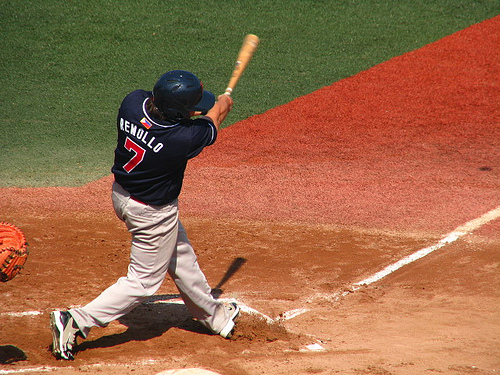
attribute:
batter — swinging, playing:
[51, 70, 239, 362]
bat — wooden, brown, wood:
[223, 32, 259, 95]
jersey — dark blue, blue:
[112, 90, 217, 207]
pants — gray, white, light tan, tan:
[68, 180, 220, 337]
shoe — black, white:
[50, 309, 78, 360]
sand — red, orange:
[4, 15, 499, 374]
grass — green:
[0, 1, 499, 188]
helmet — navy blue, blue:
[149, 69, 216, 117]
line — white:
[275, 206, 498, 325]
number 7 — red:
[123, 137, 145, 172]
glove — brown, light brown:
[1, 221, 27, 281]